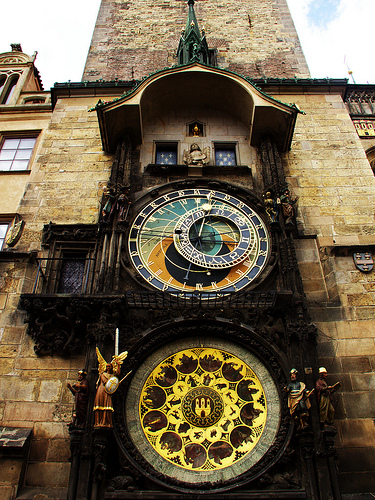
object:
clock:
[138, 345, 269, 471]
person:
[314, 366, 336, 432]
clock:
[127, 188, 268, 302]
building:
[1, 0, 374, 498]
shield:
[352, 250, 375, 276]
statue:
[282, 367, 311, 432]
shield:
[104, 375, 118, 395]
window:
[9, 159, 31, 173]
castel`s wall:
[0, 91, 375, 498]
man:
[182, 141, 208, 169]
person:
[91, 346, 129, 429]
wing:
[110, 348, 128, 376]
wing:
[94, 346, 109, 374]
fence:
[31, 254, 97, 294]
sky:
[0, 0, 375, 88]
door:
[0, 70, 21, 106]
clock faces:
[126, 174, 278, 302]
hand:
[327, 384, 332, 391]